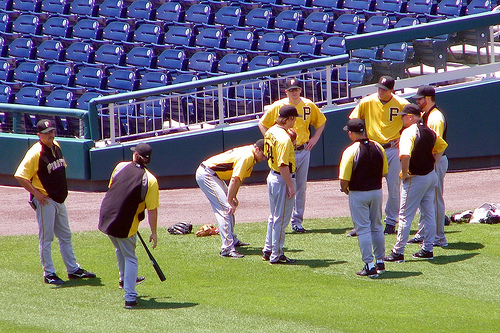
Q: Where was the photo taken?
A: A baseball field.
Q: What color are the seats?
A: Blue.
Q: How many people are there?
A: Nine.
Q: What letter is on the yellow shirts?
A: P.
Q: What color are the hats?
A: Black.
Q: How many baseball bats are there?
A: One.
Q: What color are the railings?
A: Green.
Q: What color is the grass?
A: Green.